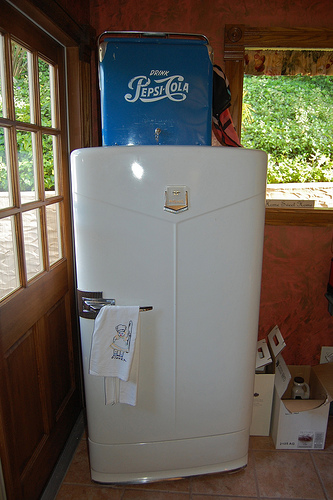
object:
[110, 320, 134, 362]
cartoon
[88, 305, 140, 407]
dish towel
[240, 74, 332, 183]
plants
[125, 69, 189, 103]
logo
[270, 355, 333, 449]
carton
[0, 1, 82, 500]
frame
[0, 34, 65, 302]
window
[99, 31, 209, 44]
silver handle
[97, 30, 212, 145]
pepsi box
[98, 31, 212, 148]
blue container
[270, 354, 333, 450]
box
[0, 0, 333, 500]
building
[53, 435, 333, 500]
tile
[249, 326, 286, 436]
box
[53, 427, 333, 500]
floor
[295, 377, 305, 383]
cap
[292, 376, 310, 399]
bottle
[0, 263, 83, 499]
plywood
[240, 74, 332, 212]
window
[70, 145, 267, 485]
fridge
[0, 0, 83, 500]
door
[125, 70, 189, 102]
pepsi cola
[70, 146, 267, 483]
on fridge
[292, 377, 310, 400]
jug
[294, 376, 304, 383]
lid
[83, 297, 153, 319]
door handle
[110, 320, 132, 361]
image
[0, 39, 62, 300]
glass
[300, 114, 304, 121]
leaf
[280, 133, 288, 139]
leaf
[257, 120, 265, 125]
leaf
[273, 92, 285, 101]
leaf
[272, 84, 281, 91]
leaf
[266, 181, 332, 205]
sand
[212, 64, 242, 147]
clothing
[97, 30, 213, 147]
cooler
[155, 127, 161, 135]
spout